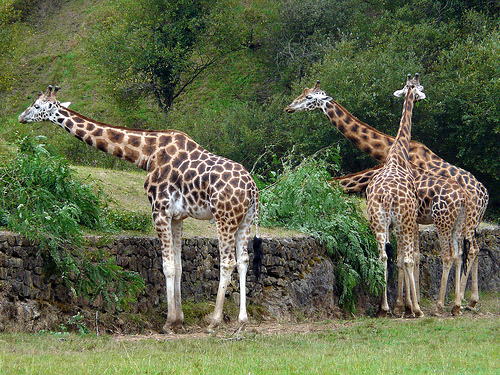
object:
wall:
[0, 232, 334, 334]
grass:
[0, 305, 500, 375]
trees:
[133, 0, 211, 111]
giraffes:
[364, 73, 427, 320]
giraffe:
[17, 84, 265, 334]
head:
[17, 84, 61, 125]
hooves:
[157, 326, 177, 334]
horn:
[44, 84, 53, 97]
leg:
[151, 200, 177, 336]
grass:
[68, 164, 150, 213]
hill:
[0, 163, 499, 237]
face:
[18, 99, 48, 125]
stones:
[34, 266, 43, 275]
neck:
[322, 99, 395, 164]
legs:
[203, 220, 237, 334]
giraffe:
[281, 80, 490, 312]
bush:
[252, 143, 387, 320]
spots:
[183, 169, 197, 182]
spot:
[155, 148, 172, 167]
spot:
[327, 110, 335, 119]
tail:
[247, 174, 267, 285]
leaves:
[297, 199, 303, 206]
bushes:
[118, 211, 153, 233]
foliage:
[44, 215, 51, 220]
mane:
[61, 104, 191, 139]